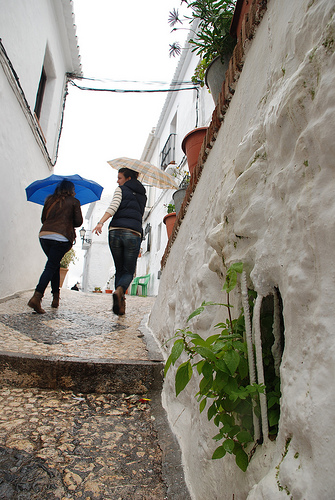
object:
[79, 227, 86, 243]
light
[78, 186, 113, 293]
building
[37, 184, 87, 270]
girl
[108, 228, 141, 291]
pants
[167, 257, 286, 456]
plant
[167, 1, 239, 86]
plant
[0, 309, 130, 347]
diamond pattern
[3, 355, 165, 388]
step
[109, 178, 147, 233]
vest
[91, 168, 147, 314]
girl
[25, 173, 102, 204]
umbrella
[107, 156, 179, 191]
umbrella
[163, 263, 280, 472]
plants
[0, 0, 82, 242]
building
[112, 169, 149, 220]
woman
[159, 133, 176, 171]
fence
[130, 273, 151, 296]
chair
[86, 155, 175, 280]
woman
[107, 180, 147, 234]
jacket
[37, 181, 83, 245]
girl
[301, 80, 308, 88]
ground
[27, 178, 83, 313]
women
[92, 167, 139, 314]
women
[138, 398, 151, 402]
leaf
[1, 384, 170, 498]
ground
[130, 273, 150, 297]
green chair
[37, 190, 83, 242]
jacket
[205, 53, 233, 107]
pots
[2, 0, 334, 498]
rain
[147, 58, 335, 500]
wall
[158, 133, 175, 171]
balcony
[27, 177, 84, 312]
woman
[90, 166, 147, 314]
woman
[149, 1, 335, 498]
wall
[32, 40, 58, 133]
window